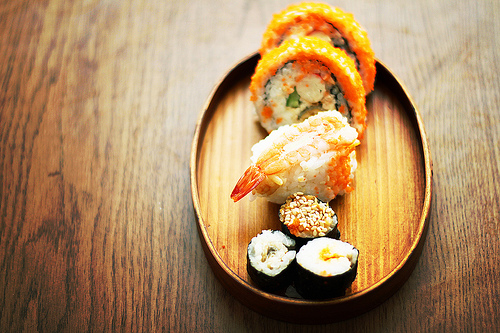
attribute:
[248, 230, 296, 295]
sushi — raw, small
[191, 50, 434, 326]
plate — wooden, oval, brown, bamboo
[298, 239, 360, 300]
sushi — raw, small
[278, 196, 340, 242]
sushi — raw, small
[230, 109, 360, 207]
sushi — raw, big, large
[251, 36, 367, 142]
sushi — raw, big, orange, round, large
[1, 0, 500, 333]
table — wooden, lined, brown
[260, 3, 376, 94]
sushi — round, large, orange